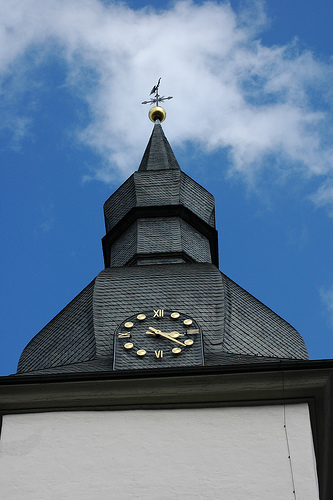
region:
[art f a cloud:
[260, 0, 322, 27]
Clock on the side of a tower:
[94, 296, 231, 366]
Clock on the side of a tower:
[109, 297, 214, 375]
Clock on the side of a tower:
[112, 313, 200, 364]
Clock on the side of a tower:
[109, 298, 202, 368]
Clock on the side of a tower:
[108, 301, 203, 374]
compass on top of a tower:
[132, 75, 177, 132]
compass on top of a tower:
[127, 70, 175, 120]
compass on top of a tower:
[136, 74, 171, 122]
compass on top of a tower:
[127, 68, 174, 128]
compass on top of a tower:
[134, 68, 185, 120]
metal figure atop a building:
[142, 74, 174, 121]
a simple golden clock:
[115, 308, 200, 358]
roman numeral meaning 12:
[151, 308, 163, 317]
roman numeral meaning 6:
[155, 350, 164, 359]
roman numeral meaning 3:
[186, 328, 200, 336]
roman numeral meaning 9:
[118, 330, 131, 336]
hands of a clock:
[147, 327, 186, 346]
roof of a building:
[0, 123, 332, 403]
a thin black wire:
[277, 360, 297, 499]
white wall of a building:
[3, 404, 320, 499]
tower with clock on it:
[18, 68, 311, 461]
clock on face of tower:
[110, 300, 201, 362]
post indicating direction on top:
[138, 72, 171, 120]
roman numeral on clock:
[152, 305, 163, 321]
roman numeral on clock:
[152, 346, 164, 361]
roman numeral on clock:
[186, 326, 200, 335]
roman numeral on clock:
[115, 330, 133, 341]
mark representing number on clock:
[136, 348, 146, 358]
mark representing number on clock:
[181, 314, 193, 327]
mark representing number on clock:
[170, 346, 183, 360]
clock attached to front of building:
[115, 310, 199, 362]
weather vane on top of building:
[144, 75, 171, 125]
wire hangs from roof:
[273, 356, 294, 495]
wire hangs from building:
[274, 356, 295, 495]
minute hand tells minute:
[150, 327, 186, 349]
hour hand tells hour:
[145, 329, 183, 336]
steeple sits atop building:
[98, 78, 222, 266]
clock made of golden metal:
[117, 306, 199, 358]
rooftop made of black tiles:
[0, 75, 332, 384]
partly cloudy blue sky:
[0, 1, 332, 343]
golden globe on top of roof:
[139, 76, 174, 122]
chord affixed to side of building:
[275, 353, 297, 498]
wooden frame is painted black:
[1, 364, 328, 417]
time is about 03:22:
[116, 306, 201, 360]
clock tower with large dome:
[0, 76, 329, 387]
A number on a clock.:
[153, 347, 162, 359]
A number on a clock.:
[185, 326, 203, 335]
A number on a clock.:
[152, 307, 165, 318]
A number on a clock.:
[117, 332, 133, 337]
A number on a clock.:
[124, 321, 133, 328]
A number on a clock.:
[136, 313, 145, 319]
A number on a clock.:
[170, 311, 181, 317]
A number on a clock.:
[182, 318, 193, 323]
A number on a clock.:
[185, 338, 193, 344]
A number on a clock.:
[172, 346, 179, 351]